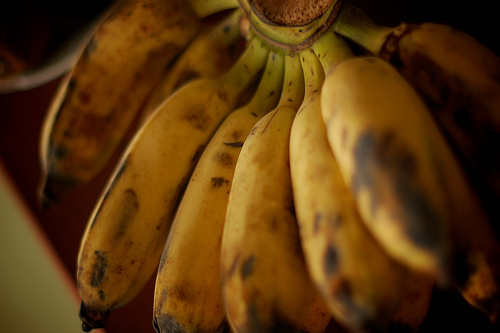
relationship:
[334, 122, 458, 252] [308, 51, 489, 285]
spots on banana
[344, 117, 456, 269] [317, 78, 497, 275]
spot on banana peel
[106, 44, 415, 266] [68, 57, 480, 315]
bunch of bananas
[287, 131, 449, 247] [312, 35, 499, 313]
spot on top of banana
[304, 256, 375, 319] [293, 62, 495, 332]
spot on top of banana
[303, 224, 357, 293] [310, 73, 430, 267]
spot on top of banana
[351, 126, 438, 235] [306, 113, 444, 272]
spot on top of banana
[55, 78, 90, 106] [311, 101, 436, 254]
black spot on top of banana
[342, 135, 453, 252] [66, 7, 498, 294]
spot on top of bananna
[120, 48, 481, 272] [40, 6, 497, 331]
bushel of bananas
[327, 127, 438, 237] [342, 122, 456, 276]
spot on peel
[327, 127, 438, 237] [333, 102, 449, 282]
spot on banana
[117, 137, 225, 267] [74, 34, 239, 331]
portion of banana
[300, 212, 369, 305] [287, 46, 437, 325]
marks on banana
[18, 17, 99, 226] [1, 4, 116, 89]
section showing sink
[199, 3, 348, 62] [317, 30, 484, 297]
stem attached to banana